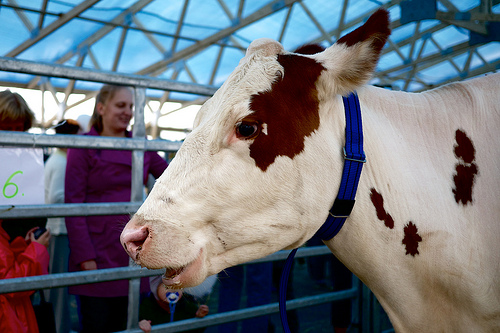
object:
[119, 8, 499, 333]
cow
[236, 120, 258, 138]
eye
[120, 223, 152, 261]
nose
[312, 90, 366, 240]
collar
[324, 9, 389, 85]
ear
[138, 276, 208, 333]
baby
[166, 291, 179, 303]
pacifier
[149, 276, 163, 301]
hat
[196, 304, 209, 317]
hand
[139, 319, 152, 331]
hand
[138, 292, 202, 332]
jacket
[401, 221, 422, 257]
spot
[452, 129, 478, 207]
spots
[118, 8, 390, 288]
head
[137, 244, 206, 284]
mouth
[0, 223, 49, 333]
coat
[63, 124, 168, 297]
coat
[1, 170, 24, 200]
number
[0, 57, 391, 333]
gate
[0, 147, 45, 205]
sign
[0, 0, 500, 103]
ceiling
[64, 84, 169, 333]
woman